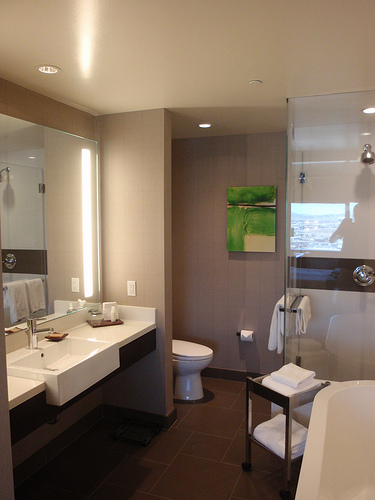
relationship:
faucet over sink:
[25, 317, 54, 350] [7, 334, 120, 404]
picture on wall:
[227, 182, 277, 254] [171, 132, 374, 381]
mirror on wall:
[0, 114, 100, 338] [2, 80, 102, 351]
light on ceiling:
[196, 120, 210, 128] [1, 1, 373, 139]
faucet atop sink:
[25, 317, 54, 350] [7, 334, 120, 404]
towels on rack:
[250, 362, 322, 460] [241, 362, 329, 484]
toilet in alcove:
[171, 338, 213, 399] [165, 110, 374, 424]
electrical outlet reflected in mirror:
[70, 276, 79, 292] [0, 114, 100, 338]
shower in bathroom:
[1, 147, 47, 328] [0, 0, 374, 497]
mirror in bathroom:
[0, 114, 100, 338] [0, 0, 374, 497]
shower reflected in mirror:
[1, 147, 47, 328] [0, 114, 100, 338]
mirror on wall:
[0, 114, 100, 338] [0, 77, 109, 463]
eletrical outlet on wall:
[124, 279, 137, 296] [96, 113, 171, 422]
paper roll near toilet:
[238, 327, 255, 343] [169, 334, 223, 404]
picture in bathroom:
[223, 180, 281, 259] [0, 0, 374, 497]